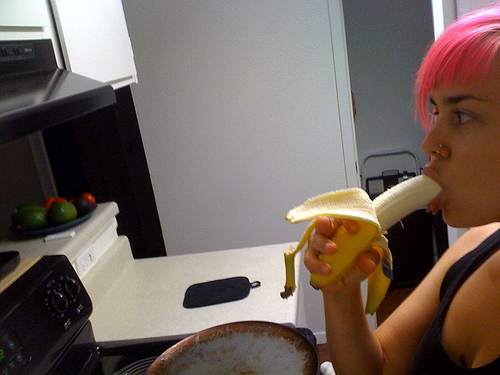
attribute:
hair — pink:
[413, 6, 499, 134]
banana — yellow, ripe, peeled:
[280, 167, 443, 315]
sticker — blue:
[381, 254, 392, 279]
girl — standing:
[303, 3, 497, 374]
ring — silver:
[436, 143, 444, 157]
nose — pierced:
[421, 115, 451, 163]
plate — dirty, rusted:
[144, 319, 319, 374]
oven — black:
[1, 251, 318, 375]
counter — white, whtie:
[87, 239, 302, 351]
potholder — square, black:
[181, 276, 262, 308]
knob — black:
[49, 288, 73, 315]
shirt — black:
[408, 225, 498, 371]